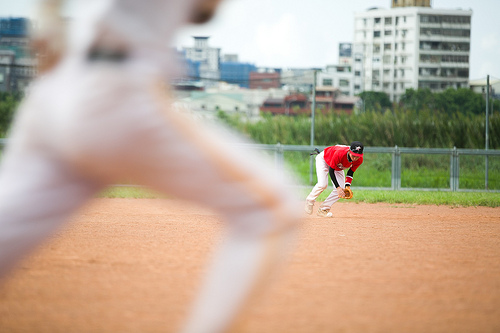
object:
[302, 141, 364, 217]
player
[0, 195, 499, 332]
field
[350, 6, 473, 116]
building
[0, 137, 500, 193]
fence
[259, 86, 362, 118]
building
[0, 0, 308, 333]
player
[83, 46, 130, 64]
belt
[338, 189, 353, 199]
glove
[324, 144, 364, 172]
shirt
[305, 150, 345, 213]
pants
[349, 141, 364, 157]
hat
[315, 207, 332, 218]
shoe